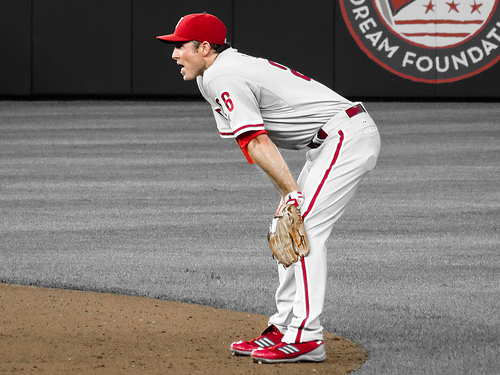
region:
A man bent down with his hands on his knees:
[155, 14, 388, 366]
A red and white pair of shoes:
[230, 314, 328, 365]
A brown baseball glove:
[264, 200, 308, 272]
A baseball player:
[154, 10, 388, 371]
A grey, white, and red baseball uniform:
[185, 30, 382, 349]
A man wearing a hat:
[152, 6, 384, 363]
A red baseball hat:
[159, 8, 233, 53]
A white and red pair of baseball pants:
[280, 106, 383, 346]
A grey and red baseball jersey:
[186, 40, 357, 152]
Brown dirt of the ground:
[1, 278, 401, 373]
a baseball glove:
[268, 216, 310, 259]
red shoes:
[253, 347, 300, 363]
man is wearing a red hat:
[158, 17, 230, 38]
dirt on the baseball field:
[84, 313, 181, 373]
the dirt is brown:
[82, 307, 174, 347]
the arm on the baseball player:
[260, 146, 283, 169]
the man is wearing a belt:
[344, 104, 363, 116]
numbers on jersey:
[212, 89, 233, 116]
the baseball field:
[21, 132, 177, 244]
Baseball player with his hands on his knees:
[154, 11, 382, 363]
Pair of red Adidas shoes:
[228, 322, 327, 365]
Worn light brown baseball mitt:
[262, 198, 310, 265]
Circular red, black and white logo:
[335, 0, 499, 85]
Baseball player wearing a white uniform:
[155, 10, 383, 364]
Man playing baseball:
[152, 8, 382, 365]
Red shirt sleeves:
[229, 123, 269, 168]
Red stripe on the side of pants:
[292, 124, 344, 344]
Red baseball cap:
[152, 10, 229, 46]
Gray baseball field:
[1, 95, 497, 372]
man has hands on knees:
[158, 6, 385, 365]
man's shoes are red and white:
[227, 322, 337, 367]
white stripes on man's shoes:
[249, 328, 300, 360]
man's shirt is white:
[188, 52, 353, 146]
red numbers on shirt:
[259, 57, 329, 103]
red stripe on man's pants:
[279, 126, 351, 344]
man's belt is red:
[291, 97, 372, 149]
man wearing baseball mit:
[259, 197, 317, 265]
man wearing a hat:
[148, 9, 232, 57]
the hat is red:
[155, 11, 232, 48]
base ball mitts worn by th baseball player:
[266, 197, 311, 267]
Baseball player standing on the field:
[151, 7, 385, 365]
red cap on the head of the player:
[152, 10, 227, 47]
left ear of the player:
[197, 36, 207, 53]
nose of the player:
[170, 46, 181, 60]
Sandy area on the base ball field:
[2, 282, 371, 374]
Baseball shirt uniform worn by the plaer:
[194, 46, 352, 151]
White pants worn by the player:
[268, 100, 384, 347]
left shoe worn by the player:
[250, 336, 329, 363]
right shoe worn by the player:
[229, 322, 284, 356]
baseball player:
[145, 8, 395, 354]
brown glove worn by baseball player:
[262, 188, 303, 280]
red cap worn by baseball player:
[140, 7, 227, 49]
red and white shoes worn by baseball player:
[236, 325, 328, 373]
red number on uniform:
[217, 89, 234, 113]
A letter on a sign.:
[400, 50, 418, 70]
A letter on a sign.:
[414, 52, 436, 72]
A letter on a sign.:
[430, 55, 450, 72]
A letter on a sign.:
[466, 46, 481, 63]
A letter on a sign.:
[479, 40, 491, 55]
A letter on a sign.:
[373, 36, 395, 56]